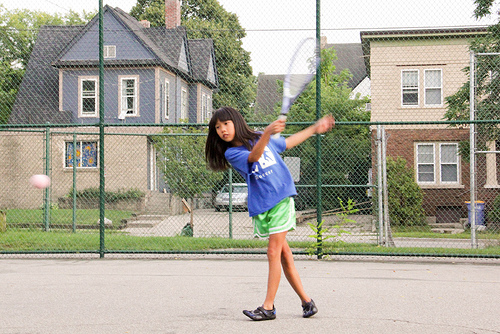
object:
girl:
[203, 106, 335, 320]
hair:
[204, 107, 262, 174]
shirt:
[223, 131, 299, 217]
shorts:
[251, 193, 297, 239]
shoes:
[244, 299, 316, 322]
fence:
[0, 1, 499, 258]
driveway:
[156, 203, 291, 241]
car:
[212, 182, 250, 214]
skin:
[283, 111, 335, 150]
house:
[0, 1, 220, 216]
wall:
[56, 64, 155, 123]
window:
[81, 74, 96, 118]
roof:
[39, 6, 214, 87]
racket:
[273, 38, 325, 140]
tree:
[126, 0, 259, 115]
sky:
[0, 0, 499, 77]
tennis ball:
[30, 174, 53, 190]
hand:
[264, 118, 290, 136]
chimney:
[163, 0, 181, 29]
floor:
[0, 258, 499, 334]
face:
[213, 111, 233, 141]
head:
[213, 105, 245, 142]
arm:
[225, 134, 279, 172]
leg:
[262, 196, 294, 308]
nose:
[218, 124, 229, 132]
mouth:
[217, 132, 231, 137]